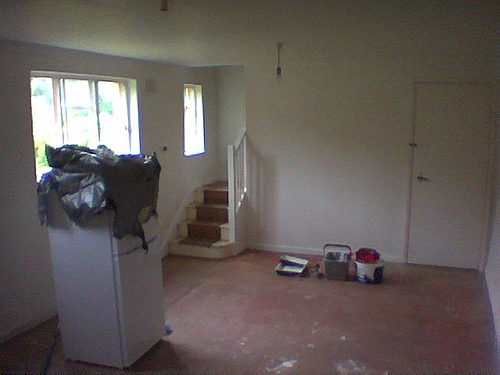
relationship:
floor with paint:
[0, 246, 499, 374] [232, 344, 397, 371]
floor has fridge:
[6, 246, 491, 372] [39, 152, 168, 369]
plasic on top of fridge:
[36, 142, 164, 255] [45, 188, 165, 368]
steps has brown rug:
[166, 181, 236, 259] [176, 190, 232, 248]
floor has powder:
[0, 246, 499, 374] [268, 358, 298, 373]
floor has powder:
[0, 246, 499, 374] [306, 343, 316, 349]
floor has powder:
[0, 246, 499, 374] [334, 360, 359, 373]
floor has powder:
[0, 246, 499, 374] [240, 342, 246, 346]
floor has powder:
[0, 246, 499, 374] [339, 336, 346, 340]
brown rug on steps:
[184, 187, 224, 246] [162, 176, 241, 261]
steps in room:
[169, 176, 243, 268] [64, 157, 329, 260]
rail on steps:
[229, 137, 246, 256] [176, 177, 228, 246]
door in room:
[402, 79, 498, 271] [4, 1, 498, 364]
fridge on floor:
[45, 163, 166, 370] [196, 289, 488, 366]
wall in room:
[264, 94, 397, 240] [4, 1, 498, 364]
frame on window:
[27, 66, 142, 181] [19, 63, 146, 185]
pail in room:
[320, 244, 349, 283] [82, 115, 328, 263]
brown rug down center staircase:
[176, 190, 232, 248] [168, 180, 252, 261]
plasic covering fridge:
[36, 142, 164, 255] [45, 163, 166, 370]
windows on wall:
[30, 75, 204, 181] [147, 93, 183, 165]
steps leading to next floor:
[166, 181, 236, 259] [203, 167, 235, 190]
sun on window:
[40, 82, 130, 147] [182, 80, 208, 155]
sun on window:
[40, 82, 130, 147] [86, 73, 133, 157]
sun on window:
[40, 82, 130, 147] [58, 75, 98, 150]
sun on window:
[40, 82, 130, 147] [28, 70, 66, 179]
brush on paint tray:
[274, 250, 313, 277] [275, 253, 312, 280]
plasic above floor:
[31, 133, 171, 255] [236, 261, 353, 361]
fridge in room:
[29, 140, 180, 374] [4, 1, 498, 364]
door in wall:
[404, 81, 497, 274] [237, 52, 488, 262]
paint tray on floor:
[273, 253, 310, 277] [201, 256, 498, 370]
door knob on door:
[406, 167, 456, 195] [415, 90, 490, 230]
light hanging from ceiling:
[262, 40, 301, 91] [18, 0, 488, 56]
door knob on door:
[414, 174, 428, 183] [389, 69, 497, 283]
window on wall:
[179, 82, 207, 159] [0, 38, 217, 345]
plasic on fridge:
[36, 142, 164, 255] [45, 188, 165, 368]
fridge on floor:
[45, 163, 166, 370] [6, 246, 491, 372]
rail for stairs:
[226, 126, 250, 256] [171, 174, 261, 263]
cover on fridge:
[40, 144, 173, 215] [38, 178, 168, 364]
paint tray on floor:
[273, 253, 310, 277] [6, 246, 491, 372]